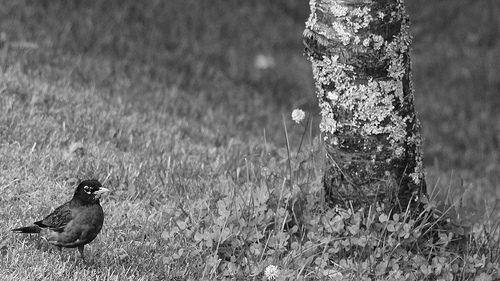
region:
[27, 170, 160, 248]
A small birdon the ground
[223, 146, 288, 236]
A small green flower leaves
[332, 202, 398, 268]
A small green flower leaves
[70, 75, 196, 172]
A thick grass ground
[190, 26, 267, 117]
A thick grass ground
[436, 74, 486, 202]
A thick grass ground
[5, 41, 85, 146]
A thick grass ground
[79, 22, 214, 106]
A thick grass ground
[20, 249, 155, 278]
A thick grass ground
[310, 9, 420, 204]
A black tree bark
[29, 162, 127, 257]
bird standing in the grass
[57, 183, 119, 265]
bird standing in the grass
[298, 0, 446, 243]
a tree trunk covered in moss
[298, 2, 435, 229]
moss on a tree trunk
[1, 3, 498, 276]
freshly cut grass surrounding a tree trunk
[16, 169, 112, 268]
a bird sitting in a field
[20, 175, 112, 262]
a bird standing on grass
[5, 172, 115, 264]
a bird next to a tree trunk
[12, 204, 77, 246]
a bird's wing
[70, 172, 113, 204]
bird has a head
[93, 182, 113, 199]
bird's beak is sharp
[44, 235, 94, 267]
bird has two legs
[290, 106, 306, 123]
light colored flower blossom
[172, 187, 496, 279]
clover growing around tree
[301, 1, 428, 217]
tree trunk growing out of ground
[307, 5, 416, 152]
light colored bark on tree trunk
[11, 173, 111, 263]
dark colored bird on the ground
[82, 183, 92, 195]
eye on bird's face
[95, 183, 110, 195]
beak on bird's face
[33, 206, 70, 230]
wing on bird's body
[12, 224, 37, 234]
tail feathers on bird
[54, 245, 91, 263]
two little legs on bird